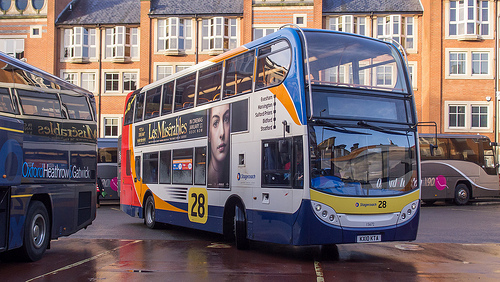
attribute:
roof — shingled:
[56, 2, 140, 24]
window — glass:
[446, 102, 468, 129]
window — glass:
[449, 0, 489, 34]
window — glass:
[449, 2, 455, 37]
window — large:
[303, 40, 398, 88]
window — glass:
[447, 106, 469, 131]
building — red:
[18, 13, 487, 197]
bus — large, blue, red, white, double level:
[115, 22, 422, 259]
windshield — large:
[311, 121, 418, 196]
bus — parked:
[0, 45, 110, 270]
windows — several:
[51, 22, 147, 102]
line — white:
[23, 235, 153, 280]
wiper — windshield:
[308, 118, 371, 145]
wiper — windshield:
[356, 115, 415, 145]